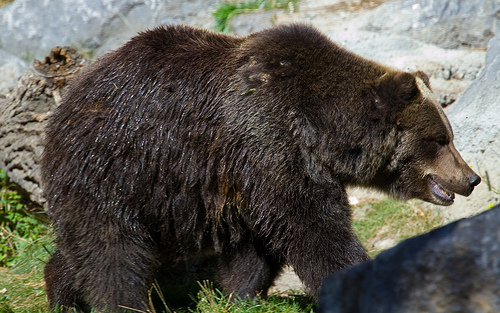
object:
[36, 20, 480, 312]
bear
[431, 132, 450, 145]
eyes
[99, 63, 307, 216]
fur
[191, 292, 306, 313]
grass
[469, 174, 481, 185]
nose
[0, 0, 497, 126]
rocks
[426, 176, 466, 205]
mouth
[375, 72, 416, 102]
ears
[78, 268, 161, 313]
feet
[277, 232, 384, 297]
front legs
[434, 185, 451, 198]
teeth